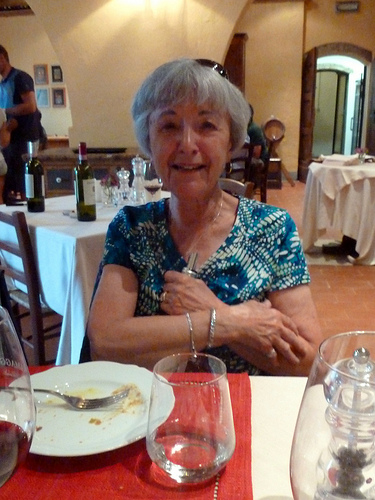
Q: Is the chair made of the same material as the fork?
A: No, the chair is made of wood and the fork is made of metal.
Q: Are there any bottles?
A: Yes, there is a bottle.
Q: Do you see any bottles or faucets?
A: Yes, there is a bottle.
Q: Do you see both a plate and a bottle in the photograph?
A: Yes, there are both a bottle and a plate.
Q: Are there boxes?
A: No, there are no boxes.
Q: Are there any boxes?
A: No, there are no boxes.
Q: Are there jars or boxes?
A: No, there are no boxes or jars.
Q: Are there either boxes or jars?
A: No, there are no boxes or jars.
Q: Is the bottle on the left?
A: Yes, the bottle is on the left of the image.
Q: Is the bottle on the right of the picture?
A: No, the bottle is on the left of the image.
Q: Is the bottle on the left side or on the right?
A: The bottle is on the left of the image.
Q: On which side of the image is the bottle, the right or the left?
A: The bottle is on the left of the image.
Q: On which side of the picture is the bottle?
A: The bottle is on the left of the image.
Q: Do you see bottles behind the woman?
A: Yes, there is a bottle behind the woman.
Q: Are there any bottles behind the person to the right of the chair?
A: Yes, there is a bottle behind the woman.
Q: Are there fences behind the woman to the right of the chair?
A: No, there is a bottle behind the woman.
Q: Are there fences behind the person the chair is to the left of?
A: No, there is a bottle behind the woman.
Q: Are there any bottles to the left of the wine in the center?
A: Yes, there is a bottle to the left of the wine.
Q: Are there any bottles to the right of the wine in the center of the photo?
A: No, the bottle is to the left of the wine.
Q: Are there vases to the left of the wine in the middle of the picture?
A: No, there is a bottle to the left of the wine.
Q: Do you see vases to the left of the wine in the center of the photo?
A: No, there is a bottle to the left of the wine.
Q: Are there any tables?
A: Yes, there is a table.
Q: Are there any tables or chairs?
A: Yes, there is a table.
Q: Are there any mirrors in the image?
A: No, there are no mirrors.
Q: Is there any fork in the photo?
A: Yes, there is a fork.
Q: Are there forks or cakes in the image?
A: Yes, there is a fork.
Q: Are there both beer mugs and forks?
A: No, there is a fork but no beer mugs.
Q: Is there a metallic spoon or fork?
A: Yes, there is a metal fork.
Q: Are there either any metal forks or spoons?
A: Yes, there is a metal fork.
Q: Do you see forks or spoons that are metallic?
A: Yes, the fork is metallic.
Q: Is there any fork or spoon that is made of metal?
A: Yes, the fork is made of metal.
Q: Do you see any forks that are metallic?
A: Yes, there is a metal fork.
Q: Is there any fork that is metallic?
A: Yes, there is a fork that is metallic.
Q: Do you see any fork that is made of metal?
A: Yes, there is a fork that is made of metal.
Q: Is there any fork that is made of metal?
A: Yes, there is a fork that is made of metal.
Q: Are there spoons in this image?
A: No, there are no spoons.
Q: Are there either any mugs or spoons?
A: No, there are no spoons or mugs.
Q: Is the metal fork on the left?
A: Yes, the fork is on the left of the image.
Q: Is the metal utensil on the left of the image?
A: Yes, the fork is on the left of the image.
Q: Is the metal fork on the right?
A: No, the fork is on the left of the image.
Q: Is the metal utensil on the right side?
A: No, the fork is on the left of the image.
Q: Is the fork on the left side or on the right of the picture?
A: The fork is on the left of the image.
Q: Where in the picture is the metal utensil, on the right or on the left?
A: The fork is on the left of the image.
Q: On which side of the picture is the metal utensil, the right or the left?
A: The fork is on the left of the image.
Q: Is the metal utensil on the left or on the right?
A: The fork is on the left of the image.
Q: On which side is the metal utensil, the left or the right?
A: The fork is on the left of the image.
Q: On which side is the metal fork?
A: The fork is on the left of the image.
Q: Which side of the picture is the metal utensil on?
A: The fork is on the left of the image.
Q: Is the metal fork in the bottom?
A: Yes, the fork is in the bottom of the image.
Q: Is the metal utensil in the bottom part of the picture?
A: Yes, the fork is in the bottom of the image.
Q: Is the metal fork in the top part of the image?
A: No, the fork is in the bottom of the image.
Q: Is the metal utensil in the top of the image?
A: No, the fork is in the bottom of the image.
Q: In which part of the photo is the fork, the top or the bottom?
A: The fork is in the bottom of the image.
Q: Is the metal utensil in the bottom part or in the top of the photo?
A: The fork is in the bottom of the image.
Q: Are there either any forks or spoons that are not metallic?
A: No, there is a fork but it is metallic.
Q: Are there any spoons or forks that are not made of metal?
A: No, there is a fork but it is made of metal.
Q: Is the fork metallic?
A: Yes, the fork is metallic.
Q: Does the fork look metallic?
A: Yes, the fork is metallic.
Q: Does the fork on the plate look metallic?
A: Yes, the fork is metallic.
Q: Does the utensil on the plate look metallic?
A: Yes, the fork is metallic.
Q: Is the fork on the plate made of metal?
A: Yes, the fork is made of metal.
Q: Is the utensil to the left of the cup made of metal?
A: Yes, the fork is made of metal.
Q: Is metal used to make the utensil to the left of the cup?
A: Yes, the fork is made of metal.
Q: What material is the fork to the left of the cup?
A: The fork is made of metal.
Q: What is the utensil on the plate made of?
A: The fork is made of metal.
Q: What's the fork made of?
A: The fork is made of metal.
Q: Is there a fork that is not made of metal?
A: No, there is a fork but it is made of metal.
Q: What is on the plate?
A: The fork is on the plate.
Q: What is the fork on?
A: The fork is on the plate.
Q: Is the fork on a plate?
A: Yes, the fork is on a plate.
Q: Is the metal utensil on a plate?
A: Yes, the fork is on a plate.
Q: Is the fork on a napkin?
A: No, the fork is on a plate.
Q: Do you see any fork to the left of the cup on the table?
A: Yes, there is a fork to the left of the cup.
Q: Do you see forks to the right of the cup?
A: No, the fork is to the left of the cup.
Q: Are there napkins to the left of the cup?
A: No, there is a fork to the left of the cup.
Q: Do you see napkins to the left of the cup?
A: No, there is a fork to the left of the cup.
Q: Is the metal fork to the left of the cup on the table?
A: Yes, the fork is to the left of the cup.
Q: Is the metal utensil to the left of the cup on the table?
A: Yes, the fork is to the left of the cup.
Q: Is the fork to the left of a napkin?
A: No, the fork is to the left of the cup.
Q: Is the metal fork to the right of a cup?
A: No, the fork is to the left of a cup.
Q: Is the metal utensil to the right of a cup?
A: No, the fork is to the left of a cup.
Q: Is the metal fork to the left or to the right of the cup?
A: The fork is to the left of the cup.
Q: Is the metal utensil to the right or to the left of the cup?
A: The fork is to the left of the cup.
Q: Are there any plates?
A: Yes, there is a plate.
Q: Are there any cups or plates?
A: Yes, there is a plate.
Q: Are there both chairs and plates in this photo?
A: Yes, there are both a plate and a chair.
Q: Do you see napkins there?
A: No, there are no napkins.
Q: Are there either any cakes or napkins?
A: No, there are no napkins or cakes.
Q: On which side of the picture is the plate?
A: The plate is on the left of the image.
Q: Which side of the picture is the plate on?
A: The plate is on the left of the image.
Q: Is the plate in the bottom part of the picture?
A: Yes, the plate is in the bottom of the image.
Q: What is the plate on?
A: The plate is on the table.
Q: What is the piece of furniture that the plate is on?
A: The piece of furniture is a table.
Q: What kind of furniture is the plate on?
A: The plate is on the table.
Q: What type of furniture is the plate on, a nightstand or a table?
A: The plate is on a table.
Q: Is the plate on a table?
A: Yes, the plate is on a table.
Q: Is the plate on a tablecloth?
A: No, the plate is on a table.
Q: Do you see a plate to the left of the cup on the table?
A: Yes, there is a plate to the left of the cup.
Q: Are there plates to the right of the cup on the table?
A: No, the plate is to the left of the cup.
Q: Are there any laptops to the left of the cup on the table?
A: No, there is a plate to the left of the cup.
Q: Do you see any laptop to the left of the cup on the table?
A: No, there is a plate to the left of the cup.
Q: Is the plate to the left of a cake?
A: No, the plate is to the left of a cup.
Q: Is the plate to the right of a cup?
A: No, the plate is to the left of a cup.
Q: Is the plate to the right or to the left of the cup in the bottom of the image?
A: The plate is to the left of the cup.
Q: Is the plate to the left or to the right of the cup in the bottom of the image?
A: The plate is to the left of the cup.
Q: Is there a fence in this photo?
A: No, there are no fences.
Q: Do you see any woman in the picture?
A: Yes, there is a woman.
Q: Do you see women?
A: Yes, there is a woman.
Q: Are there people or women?
A: Yes, there is a woman.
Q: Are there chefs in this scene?
A: No, there are no chefs.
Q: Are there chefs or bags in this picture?
A: No, there are no chefs or bags.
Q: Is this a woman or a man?
A: This is a woman.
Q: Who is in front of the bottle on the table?
A: The woman is in front of the bottle.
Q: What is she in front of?
A: The woman is in front of the bottle.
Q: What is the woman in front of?
A: The woman is in front of the bottle.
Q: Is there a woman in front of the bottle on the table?
A: Yes, there is a woman in front of the bottle.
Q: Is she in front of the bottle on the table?
A: Yes, the woman is in front of the bottle.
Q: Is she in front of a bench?
A: No, the woman is in front of the bottle.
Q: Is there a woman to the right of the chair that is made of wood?
A: Yes, there is a woman to the right of the chair.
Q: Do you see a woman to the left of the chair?
A: No, the woman is to the right of the chair.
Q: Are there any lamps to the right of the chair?
A: No, there is a woman to the right of the chair.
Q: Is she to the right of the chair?
A: Yes, the woman is to the right of the chair.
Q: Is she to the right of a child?
A: No, the woman is to the right of the chair.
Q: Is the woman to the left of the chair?
A: No, the woman is to the right of the chair.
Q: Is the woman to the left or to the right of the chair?
A: The woman is to the right of the chair.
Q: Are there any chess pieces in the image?
A: No, there are no chess pieces.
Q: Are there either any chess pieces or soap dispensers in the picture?
A: No, there are no chess pieces or soap dispensers.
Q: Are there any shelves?
A: No, there are no shelves.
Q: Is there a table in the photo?
A: Yes, there is a table.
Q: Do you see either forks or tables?
A: Yes, there is a table.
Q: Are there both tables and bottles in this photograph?
A: Yes, there are both a table and a bottle.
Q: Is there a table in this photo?
A: Yes, there is a table.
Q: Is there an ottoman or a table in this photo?
A: Yes, there is a table.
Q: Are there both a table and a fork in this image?
A: Yes, there are both a table and a fork.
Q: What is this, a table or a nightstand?
A: This is a table.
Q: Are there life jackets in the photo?
A: No, there are no life jackets.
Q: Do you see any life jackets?
A: No, there are no life jackets.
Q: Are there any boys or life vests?
A: No, there are no life vests or boys.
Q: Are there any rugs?
A: No, there are no rugs.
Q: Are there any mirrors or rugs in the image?
A: No, there are no rugs or mirrors.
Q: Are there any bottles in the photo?
A: Yes, there is a bottle.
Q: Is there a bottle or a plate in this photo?
A: Yes, there is a bottle.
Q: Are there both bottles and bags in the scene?
A: No, there is a bottle but no bags.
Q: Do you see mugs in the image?
A: No, there are no mugs.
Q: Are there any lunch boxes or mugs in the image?
A: No, there are no mugs or lunch boxes.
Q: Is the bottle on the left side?
A: Yes, the bottle is on the left of the image.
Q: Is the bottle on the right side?
A: No, the bottle is on the left of the image.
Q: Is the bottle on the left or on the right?
A: The bottle is on the left of the image.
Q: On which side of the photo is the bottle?
A: The bottle is on the left of the image.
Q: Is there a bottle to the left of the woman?
A: Yes, there is a bottle to the left of the woman.